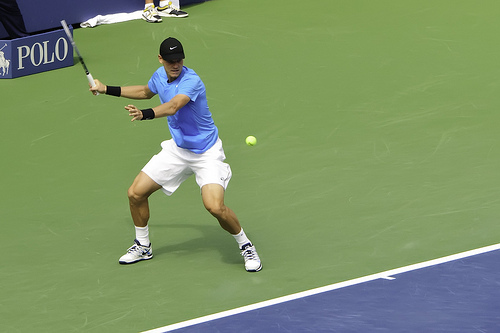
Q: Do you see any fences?
A: No, there are no fences.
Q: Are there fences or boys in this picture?
A: No, there are no fences or boys.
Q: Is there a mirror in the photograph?
A: No, there are no mirrors.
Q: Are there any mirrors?
A: No, there are no mirrors.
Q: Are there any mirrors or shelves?
A: No, there are no mirrors or shelves.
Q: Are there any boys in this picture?
A: No, there are no boys.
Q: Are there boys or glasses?
A: No, there are no boys or glasses.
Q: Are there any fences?
A: No, there are no fences.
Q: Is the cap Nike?
A: Yes, the cap is nike.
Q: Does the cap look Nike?
A: Yes, the cap is nike.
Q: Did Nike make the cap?
A: Yes, the cap was made by nike.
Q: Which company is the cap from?
A: The cap is from nike.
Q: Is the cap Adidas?
A: No, the cap is nike.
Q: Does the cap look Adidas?
A: No, the cap is nike.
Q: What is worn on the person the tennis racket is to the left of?
A: The cap is worn on the man.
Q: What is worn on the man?
A: The cap is worn on the man.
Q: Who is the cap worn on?
A: The cap is worn on the man.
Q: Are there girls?
A: No, there are no girls.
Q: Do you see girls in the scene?
A: No, there are no girls.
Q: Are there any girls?
A: No, there are no girls.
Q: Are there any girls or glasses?
A: No, there are no girls or glasses.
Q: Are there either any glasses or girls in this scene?
A: No, there are no girls or glasses.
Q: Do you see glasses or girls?
A: No, there are no girls or glasses.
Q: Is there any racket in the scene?
A: Yes, there is a racket.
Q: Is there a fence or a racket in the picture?
A: Yes, there is a racket.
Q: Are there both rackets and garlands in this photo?
A: No, there is a racket but no garlands.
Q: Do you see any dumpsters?
A: No, there are no dumpsters.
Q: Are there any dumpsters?
A: No, there are no dumpsters.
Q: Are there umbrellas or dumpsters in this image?
A: No, there are no dumpsters or umbrellas.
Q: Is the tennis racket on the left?
A: Yes, the tennis racket is on the left of the image.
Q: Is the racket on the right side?
A: No, the racket is on the left of the image.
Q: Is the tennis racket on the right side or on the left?
A: The tennis racket is on the left of the image.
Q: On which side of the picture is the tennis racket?
A: The tennis racket is on the left of the image.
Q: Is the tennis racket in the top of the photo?
A: Yes, the tennis racket is in the top of the image.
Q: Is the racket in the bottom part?
A: No, the racket is in the top of the image.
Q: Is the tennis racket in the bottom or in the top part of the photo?
A: The tennis racket is in the top of the image.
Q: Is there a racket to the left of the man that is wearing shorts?
A: Yes, there is a racket to the left of the man.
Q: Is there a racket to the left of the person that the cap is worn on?
A: Yes, there is a racket to the left of the man.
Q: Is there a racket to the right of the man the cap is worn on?
A: No, the racket is to the left of the man.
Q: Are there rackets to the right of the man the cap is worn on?
A: No, the racket is to the left of the man.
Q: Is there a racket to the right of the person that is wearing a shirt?
A: No, the racket is to the left of the man.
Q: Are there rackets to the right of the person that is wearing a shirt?
A: No, the racket is to the left of the man.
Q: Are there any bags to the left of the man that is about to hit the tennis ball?
A: No, there is a racket to the left of the man.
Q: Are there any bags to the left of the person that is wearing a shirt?
A: No, there is a racket to the left of the man.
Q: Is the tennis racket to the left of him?
A: Yes, the tennis racket is to the left of a man.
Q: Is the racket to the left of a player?
A: No, the racket is to the left of a man.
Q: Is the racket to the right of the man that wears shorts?
A: No, the racket is to the left of the man.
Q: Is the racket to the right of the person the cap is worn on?
A: No, the racket is to the left of the man.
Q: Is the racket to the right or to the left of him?
A: The racket is to the left of the man.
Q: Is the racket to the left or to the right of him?
A: The racket is to the left of the man.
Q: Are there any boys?
A: No, there are no boys.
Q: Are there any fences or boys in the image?
A: No, there are no boys or fences.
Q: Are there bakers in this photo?
A: No, there are no bakers.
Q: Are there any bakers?
A: No, there are no bakers.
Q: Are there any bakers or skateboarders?
A: No, there are no bakers or skateboarders.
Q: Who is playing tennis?
A: The man is playing tennis.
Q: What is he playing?
A: The man is playing tennis.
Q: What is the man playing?
A: The man is playing tennis.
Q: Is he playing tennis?
A: Yes, the man is playing tennis.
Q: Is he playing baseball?
A: No, the man is playing tennis.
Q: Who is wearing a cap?
A: The man is wearing a cap.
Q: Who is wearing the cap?
A: The man is wearing a cap.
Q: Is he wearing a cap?
A: Yes, the man is wearing a cap.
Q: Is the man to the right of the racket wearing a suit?
A: No, the man is wearing a cap.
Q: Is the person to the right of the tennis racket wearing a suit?
A: No, the man is wearing a cap.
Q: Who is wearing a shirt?
A: The man is wearing a shirt.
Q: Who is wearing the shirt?
A: The man is wearing a shirt.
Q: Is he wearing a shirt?
A: Yes, the man is wearing a shirt.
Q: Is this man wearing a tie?
A: No, the man is wearing a shirt.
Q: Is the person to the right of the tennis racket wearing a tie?
A: No, the man is wearing a shirt.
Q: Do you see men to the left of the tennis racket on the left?
A: No, the man is to the right of the tennis racket.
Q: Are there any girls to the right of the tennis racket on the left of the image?
A: No, there is a man to the right of the tennis racket.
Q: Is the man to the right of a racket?
A: Yes, the man is to the right of a racket.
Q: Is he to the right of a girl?
A: No, the man is to the right of a racket.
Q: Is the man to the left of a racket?
A: No, the man is to the right of a racket.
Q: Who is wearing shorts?
A: The man is wearing shorts.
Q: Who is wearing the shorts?
A: The man is wearing shorts.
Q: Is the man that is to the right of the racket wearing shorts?
A: Yes, the man is wearing shorts.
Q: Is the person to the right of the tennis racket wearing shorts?
A: Yes, the man is wearing shorts.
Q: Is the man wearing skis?
A: No, the man is wearing shorts.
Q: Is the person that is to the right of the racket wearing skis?
A: No, the man is wearing shorts.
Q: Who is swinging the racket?
A: The man is swinging the racket.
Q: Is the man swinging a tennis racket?
A: Yes, the man is swinging a tennis racket.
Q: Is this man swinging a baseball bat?
A: No, the man is swinging a tennis racket.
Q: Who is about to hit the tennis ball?
A: The man is about to hit the tennis ball.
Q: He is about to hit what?
A: The man is about to hit the tennis ball.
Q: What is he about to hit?
A: The man is about to hit the tennis ball.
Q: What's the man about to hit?
A: The man is about to hit the tennis ball.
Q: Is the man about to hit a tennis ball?
A: Yes, the man is about to hit a tennis ball.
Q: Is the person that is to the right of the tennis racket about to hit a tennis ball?
A: Yes, the man is about to hit a tennis ball.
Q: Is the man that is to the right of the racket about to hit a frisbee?
A: No, the man is about to hit a tennis ball.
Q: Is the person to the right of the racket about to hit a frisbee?
A: No, the man is about to hit a tennis ball.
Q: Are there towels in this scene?
A: Yes, there is a towel.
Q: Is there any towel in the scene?
A: Yes, there is a towel.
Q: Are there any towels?
A: Yes, there is a towel.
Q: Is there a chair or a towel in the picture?
A: Yes, there is a towel.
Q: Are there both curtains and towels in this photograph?
A: No, there is a towel but no curtains.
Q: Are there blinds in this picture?
A: No, there are no blinds.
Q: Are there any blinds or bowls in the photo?
A: No, there are no blinds or bowls.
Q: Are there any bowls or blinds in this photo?
A: No, there are no blinds or bowls.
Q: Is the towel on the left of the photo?
A: Yes, the towel is on the left of the image.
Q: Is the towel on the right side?
A: No, the towel is on the left of the image.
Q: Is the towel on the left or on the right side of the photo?
A: The towel is on the left of the image.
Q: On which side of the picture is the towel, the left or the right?
A: The towel is on the left of the image.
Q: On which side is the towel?
A: The towel is on the left of the image.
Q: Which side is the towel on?
A: The towel is on the left of the image.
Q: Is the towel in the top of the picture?
A: Yes, the towel is in the top of the image.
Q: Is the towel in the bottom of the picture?
A: No, the towel is in the top of the image.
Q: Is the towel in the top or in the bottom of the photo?
A: The towel is in the top of the image.